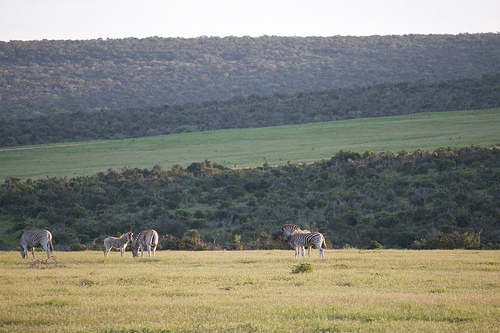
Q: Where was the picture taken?
A: In the wild.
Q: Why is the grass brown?
A: Dry.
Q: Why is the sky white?
A: Overcast.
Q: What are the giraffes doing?
A: Grazing.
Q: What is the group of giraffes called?
A: Herd.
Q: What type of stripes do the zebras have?
A: Black and white.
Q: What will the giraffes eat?
A: Plants.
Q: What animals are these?
A: Zebras.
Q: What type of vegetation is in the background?
A: Bushes and trees.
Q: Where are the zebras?
A: In a field.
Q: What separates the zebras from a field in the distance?
A: Section of bushes and trees.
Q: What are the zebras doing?
A: Grazing.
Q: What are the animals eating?
A: Grass.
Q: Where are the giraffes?
A: There are no giraffes.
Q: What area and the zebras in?
A: A grassy field.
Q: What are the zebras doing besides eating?
A: Walking.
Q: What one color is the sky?
A: White.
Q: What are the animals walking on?
A: On the grass.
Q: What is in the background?
A: Hills.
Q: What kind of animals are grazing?
A: Horses.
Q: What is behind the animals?
A: Trees.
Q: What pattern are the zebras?
A: Striped.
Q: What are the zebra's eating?
A: Grass.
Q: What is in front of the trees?
A: Zebras.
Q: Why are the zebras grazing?
A: Hunger.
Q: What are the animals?
A: Zebras.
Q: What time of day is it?
A: Daytime.